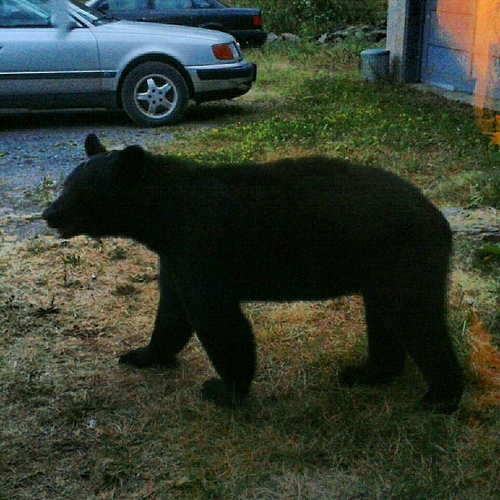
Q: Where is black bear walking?
A: Across lawn.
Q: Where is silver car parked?
A: On gravel.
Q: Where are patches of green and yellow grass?
A: Lawn.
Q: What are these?
A: Two front bear paws.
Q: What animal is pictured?
A: Bear.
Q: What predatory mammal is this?
A: Black bear.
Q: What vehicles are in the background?
A: Cars.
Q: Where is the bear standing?
A: In the grass.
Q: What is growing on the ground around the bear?
A: Grass.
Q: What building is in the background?
A: Garage.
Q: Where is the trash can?
A: Beside the garage door.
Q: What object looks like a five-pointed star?
A: Car wheel.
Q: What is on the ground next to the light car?
A: Gravel.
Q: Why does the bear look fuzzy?
A: Covered with hair.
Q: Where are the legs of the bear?
A: On the ground.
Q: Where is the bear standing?
A: On the ground.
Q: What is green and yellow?
A: The grass.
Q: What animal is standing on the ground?
A: A bear.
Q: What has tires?
A: The car.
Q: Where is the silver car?
A: Parked.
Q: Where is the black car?
A: Parked.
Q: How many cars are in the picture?
A: Two.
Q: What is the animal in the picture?
A: A bear.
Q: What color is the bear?
A: Black.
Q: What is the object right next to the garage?
A: A trash can.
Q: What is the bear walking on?
A: Grass.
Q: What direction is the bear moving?
A: To the left.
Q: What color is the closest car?
A: Silver.